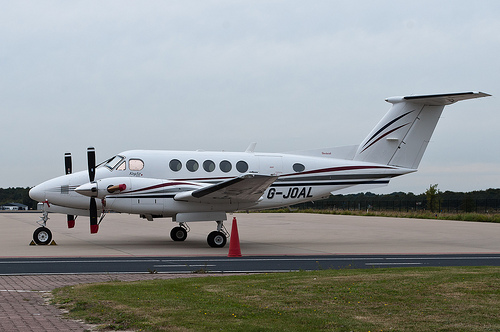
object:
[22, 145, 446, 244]
plane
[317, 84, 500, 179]
tail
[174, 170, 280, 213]
wing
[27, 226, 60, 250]
wheel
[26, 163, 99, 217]
nose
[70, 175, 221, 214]
engine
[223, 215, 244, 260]
cone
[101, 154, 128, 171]
windshield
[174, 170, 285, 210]
left wing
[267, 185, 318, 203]
name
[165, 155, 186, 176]
window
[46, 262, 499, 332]
grass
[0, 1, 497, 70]
sky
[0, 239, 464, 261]
runway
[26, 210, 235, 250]
landing gear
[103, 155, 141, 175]
cockpit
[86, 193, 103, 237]
propeller